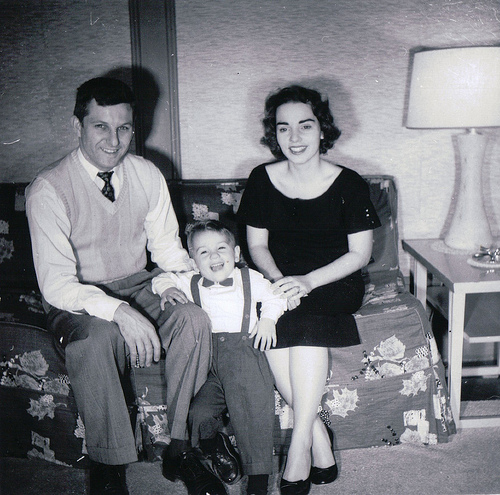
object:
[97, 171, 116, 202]
tie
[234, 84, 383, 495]
woman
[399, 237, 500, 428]
table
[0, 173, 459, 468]
couch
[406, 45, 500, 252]
lamp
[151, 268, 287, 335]
suspenders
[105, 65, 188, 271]
shadow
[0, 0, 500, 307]
wall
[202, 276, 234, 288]
bowtie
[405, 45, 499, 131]
lamp shade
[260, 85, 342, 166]
head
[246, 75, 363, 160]
shadow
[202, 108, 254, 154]
wall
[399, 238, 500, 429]
end table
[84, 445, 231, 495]
shoes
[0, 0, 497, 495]
picture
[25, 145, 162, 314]
sweater vest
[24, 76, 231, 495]
man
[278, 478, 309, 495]
shoe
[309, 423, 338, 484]
shoe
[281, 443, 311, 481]
foot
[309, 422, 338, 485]
foot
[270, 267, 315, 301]
hand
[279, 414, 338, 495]
shoes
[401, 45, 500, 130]
shade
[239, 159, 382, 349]
dress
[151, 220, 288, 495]
boy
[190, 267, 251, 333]
suspenders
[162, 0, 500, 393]
wall